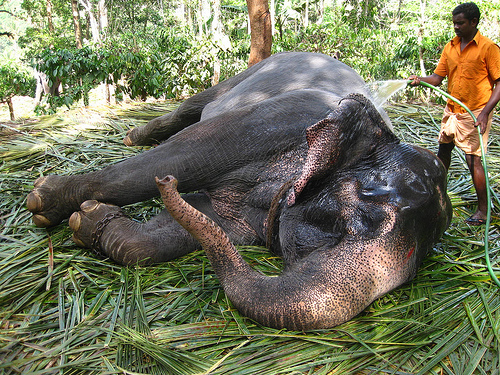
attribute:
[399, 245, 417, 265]
dot — red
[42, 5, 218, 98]
trees — green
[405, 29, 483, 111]
shirt — orange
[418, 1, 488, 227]
man — spraying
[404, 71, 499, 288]
hose — green, garden hose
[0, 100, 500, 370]
fronds — palm fronds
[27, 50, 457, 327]
elephant — getting bath, getting sprayed, laying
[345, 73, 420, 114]
water — spraying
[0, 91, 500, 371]
leaves — palm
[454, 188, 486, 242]
flip flot — black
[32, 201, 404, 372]
ground — covered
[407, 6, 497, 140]
man — watering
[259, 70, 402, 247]
ear — elephant's ear, right ear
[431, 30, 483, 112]
shirt — orange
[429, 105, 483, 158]
shorts — peach